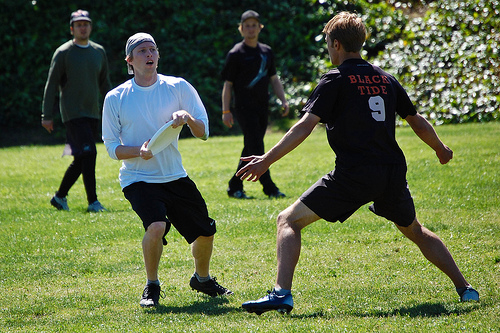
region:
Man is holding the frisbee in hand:
[98, 30, 211, 192]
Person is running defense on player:
[304, 56, 421, 187]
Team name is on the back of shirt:
[340, 64, 400, 165]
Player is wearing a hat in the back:
[60, 7, 100, 49]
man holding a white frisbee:
[93, 22, 240, 315]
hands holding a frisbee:
[136, 105, 197, 162]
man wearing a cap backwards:
[91, 23, 239, 318]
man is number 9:
[227, 5, 487, 324]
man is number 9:
[270, 5, 435, 155]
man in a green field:
[2, 3, 498, 330]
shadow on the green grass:
[307, 280, 450, 327]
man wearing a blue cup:
[39, 6, 119, 87]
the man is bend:
[97, 25, 244, 317]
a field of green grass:
[0, 120, 499, 331]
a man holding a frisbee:
[100, 32, 232, 307]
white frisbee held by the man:
[145, 118, 182, 155]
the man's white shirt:
[101, 73, 208, 190]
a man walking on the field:
[42, 9, 112, 212]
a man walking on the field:
[218, 10, 288, 197]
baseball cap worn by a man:
[125, 33, 156, 74]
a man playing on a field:
[235, 10, 479, 314]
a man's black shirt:
[301, 58, 416, 178]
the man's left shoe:
[250, 285, 307, 323]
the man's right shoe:
[457, 285, 477, 301]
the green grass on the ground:
[31, 251, 71, 296]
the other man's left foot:
[139, 275, 166, 312]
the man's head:
[122, 45, 167, 78]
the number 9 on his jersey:
[361, 99, 402, 134]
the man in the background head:
[231, 12, 266, 46]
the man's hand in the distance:
[38, 120, 56, 139]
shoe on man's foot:
[458, 288, 480, 305]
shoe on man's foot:
[238, 292, 297, 314]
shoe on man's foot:
[188, 275, 231, 295]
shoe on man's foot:
[138, 283, 169, 311]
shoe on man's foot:
[47, 193, 70, 210]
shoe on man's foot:
[85, 202, 114, 213]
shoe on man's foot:
[228, 188, 252, 201]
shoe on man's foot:
[267, 190, 284, 199]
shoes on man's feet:
[240, 288, 480, 315]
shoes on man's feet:
[136, 273, 232, 308]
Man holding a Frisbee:
[100, 29, 233, 308]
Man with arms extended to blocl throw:
[236, 10, 480, 312]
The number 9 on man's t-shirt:
[367, 93, 389, 123]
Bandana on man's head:
[117, 33, 155, 73]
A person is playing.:
[265, 18, 477, 302]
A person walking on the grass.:
[43, 6, 118, 211]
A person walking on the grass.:
[256, 17, 476, 310]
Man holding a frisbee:
[100, 32, 233, 308]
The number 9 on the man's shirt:
[366, 85, 388, 126]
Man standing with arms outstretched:
[234, 8, 479, 318]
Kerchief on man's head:
[120, 31, 159, 69]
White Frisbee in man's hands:
[136, 113, 185, 158]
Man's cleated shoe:
[238, 287, 292, 316]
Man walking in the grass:
[37, 2, 107, 217]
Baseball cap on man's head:
[63, 8, 94, 20]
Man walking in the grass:
[218, 7, 281, 202]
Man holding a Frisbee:
[99, 29, 231, 312]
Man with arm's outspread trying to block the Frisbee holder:
[233, 9, 483, 317]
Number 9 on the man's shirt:
[368, 91, 386, 125]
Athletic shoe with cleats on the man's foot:
[239, 286, 296, 316]